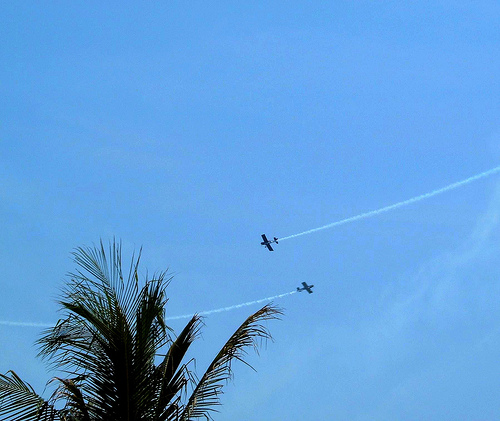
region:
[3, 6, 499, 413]
the blue sky above everything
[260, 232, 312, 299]
the two planes in the sky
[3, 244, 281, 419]
the palm tree down on the bottom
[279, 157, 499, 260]
the trail of smoke behind the plane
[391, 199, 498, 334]
the remains of a white cloud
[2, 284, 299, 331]
another long line of smoke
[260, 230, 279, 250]
the plane going to the left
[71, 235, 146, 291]
the top end of the tree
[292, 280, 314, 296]
the tree going towards the right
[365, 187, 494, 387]
another part of the sky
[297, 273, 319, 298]
a plane is flying away from the camera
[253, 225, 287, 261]
A plane is flying towards the camera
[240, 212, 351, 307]
Two planes are flying in the sky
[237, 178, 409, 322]
Two airplanes are flying in the sky with a white trail of smoke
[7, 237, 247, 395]
A green palm tree is standing straight up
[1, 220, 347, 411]
Two planes are flying in the sky and a palm tree sits below them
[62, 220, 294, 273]
An airplane with a trail of white smoke is flying over a palm tree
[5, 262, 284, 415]
A palm tree is blowing in the wind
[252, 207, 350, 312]
Two airplanes are flying low in the sky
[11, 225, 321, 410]
Two airplanes are flying low in the sky and a palm tree is blowing in the wind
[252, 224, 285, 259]
a plane in the sky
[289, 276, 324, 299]
a plane in the sky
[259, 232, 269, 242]
the wing of a plane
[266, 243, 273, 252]
the wing of a plane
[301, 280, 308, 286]
the wing of a plane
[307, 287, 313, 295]
the wing of a plane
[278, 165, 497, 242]
white smoke from the plane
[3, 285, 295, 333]
white smoke from the plane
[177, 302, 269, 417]
the branch of a green tree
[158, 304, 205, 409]
the branch of a green tree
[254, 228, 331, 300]
two planes in sky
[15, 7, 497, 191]
the sky is blue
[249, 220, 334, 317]
two planes are seen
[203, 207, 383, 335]
two trails are seen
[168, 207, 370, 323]
the trails are white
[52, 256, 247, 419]
the tree is palm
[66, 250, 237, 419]
only one tree is shown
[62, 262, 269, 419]
the leaves are green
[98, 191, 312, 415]
tree is below plane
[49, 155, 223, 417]
sky is above tree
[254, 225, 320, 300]
Two planes in the sky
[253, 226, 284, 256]
Plane fly to the left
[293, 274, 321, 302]
Plane fly to the right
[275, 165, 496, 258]
Plane contrails is white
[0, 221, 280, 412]
Palm is green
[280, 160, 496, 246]
Plane contrails on right side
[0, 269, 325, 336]
Plane contrails on left side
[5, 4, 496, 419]
Sky is blue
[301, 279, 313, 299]
Wings of plane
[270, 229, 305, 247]
Contrails exit from tail of plane